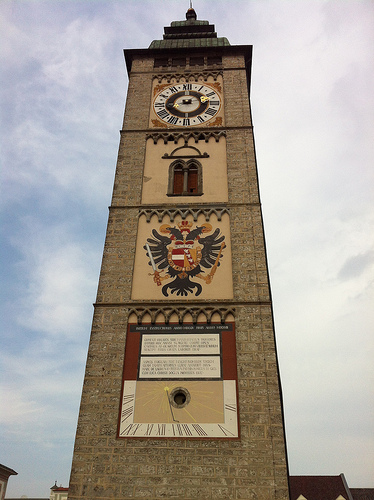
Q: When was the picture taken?
A: During the day.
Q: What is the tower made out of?
A: Brick.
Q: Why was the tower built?
A: To display the time.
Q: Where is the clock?
A: At the top of the tower.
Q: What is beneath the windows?
A: A crest.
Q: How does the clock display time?
A: With the clock hands.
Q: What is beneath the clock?
A: Windows.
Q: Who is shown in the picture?
A: No one.